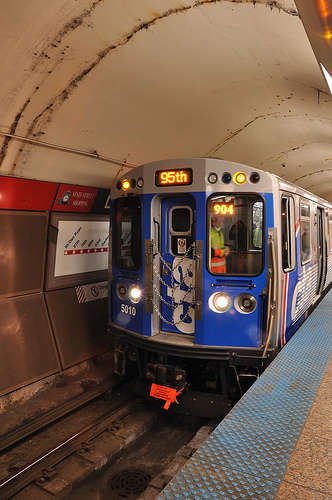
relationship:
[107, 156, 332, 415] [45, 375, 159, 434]
train on tracks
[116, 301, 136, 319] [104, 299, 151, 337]
number on left corner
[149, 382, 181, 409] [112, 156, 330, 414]
orange sign on bottom of train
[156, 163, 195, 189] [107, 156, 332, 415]
led display on train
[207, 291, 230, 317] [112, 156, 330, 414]
headlight on train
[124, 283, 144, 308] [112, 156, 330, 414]
headlight on train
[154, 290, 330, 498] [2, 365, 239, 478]
blue edge on track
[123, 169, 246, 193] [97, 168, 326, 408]
rear lights of train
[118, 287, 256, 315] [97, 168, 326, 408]
rear lights of train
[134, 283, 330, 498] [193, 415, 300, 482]
floor with tile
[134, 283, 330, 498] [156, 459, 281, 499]
floor with tile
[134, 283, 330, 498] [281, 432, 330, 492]
floor with tile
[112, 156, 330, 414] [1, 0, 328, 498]
train in photo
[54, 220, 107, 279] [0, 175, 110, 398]
posters on wall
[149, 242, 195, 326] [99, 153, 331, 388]
chains on train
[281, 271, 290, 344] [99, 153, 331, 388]
stripe on train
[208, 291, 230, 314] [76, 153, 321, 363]
headlight of train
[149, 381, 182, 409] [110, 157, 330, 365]
red tag on front of train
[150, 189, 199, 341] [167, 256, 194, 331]
door on letters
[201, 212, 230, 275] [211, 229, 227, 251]
person in vest